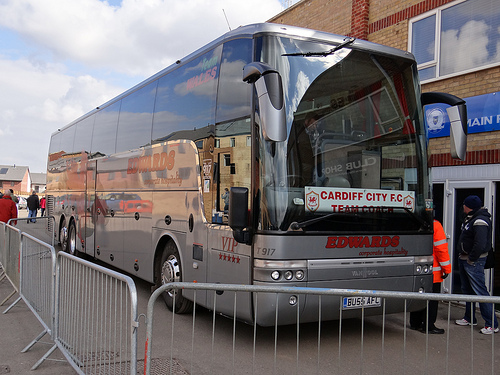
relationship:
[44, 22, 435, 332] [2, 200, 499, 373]
bus on street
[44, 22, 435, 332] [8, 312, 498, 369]
bus on road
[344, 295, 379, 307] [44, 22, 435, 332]
license plate on front of a bus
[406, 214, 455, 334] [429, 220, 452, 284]
man wearing coat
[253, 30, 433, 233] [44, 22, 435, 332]
windshield of bus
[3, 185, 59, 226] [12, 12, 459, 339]
people standing behind bus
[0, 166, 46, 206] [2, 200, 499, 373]
houses across street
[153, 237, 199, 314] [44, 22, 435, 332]
tire of bus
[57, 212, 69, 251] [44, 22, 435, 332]
tire of bus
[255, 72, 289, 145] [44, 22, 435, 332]
mirror of bus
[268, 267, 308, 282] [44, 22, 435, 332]
headlights of bus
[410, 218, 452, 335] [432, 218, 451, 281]
man in jacket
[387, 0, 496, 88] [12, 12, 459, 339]
windows of bus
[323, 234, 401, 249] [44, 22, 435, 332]
company letters on bus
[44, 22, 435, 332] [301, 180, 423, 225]
bus has sign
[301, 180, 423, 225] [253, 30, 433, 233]
sign in windshield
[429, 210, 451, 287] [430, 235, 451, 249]
coat has stripe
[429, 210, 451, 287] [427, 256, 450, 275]
coat has stripe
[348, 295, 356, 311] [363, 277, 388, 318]
letter on license plate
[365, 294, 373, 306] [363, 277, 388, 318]
letter on license plate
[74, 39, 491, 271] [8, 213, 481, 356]
bus on road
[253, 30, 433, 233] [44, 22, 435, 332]
windshield on bus